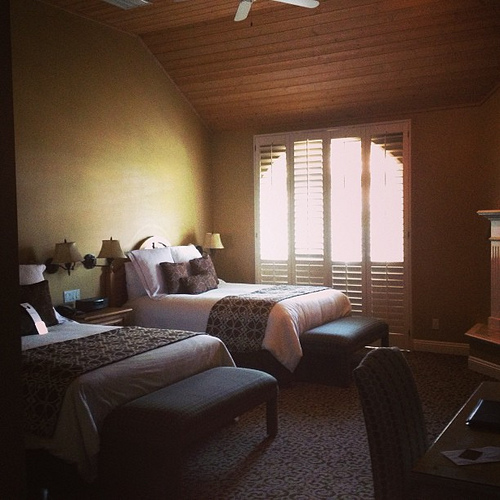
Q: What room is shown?
A: Bedroom.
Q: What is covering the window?
A: Blinds.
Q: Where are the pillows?
A: Beds.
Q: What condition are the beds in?
A: Made.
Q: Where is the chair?
A: At the desk.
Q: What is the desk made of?
A: Wood.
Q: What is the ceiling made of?
A: Wood.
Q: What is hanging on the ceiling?
A: Ceiling fan.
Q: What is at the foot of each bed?
A: Bench.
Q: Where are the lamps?
A: Hanging on the wall.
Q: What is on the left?
A: Wall.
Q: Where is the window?
A: On the wall.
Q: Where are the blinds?
A: On the window.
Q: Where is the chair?
A: At the desk.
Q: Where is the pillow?
A: On the bed.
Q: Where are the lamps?
A: On the table.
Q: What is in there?
A: Beds.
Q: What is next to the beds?
A: Night table.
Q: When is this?
A: Daytime.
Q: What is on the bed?
A: Pillows.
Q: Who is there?
A: No one.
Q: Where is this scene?
A: Bedroom.